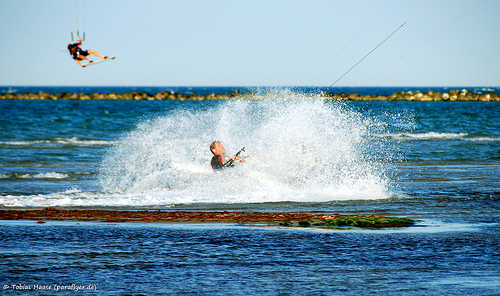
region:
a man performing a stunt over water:
[36, 22, 111, 65]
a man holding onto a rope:
[167, 100, 342, 201]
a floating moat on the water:
[57, 205, 420, 240]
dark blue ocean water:
[156, 235, 331, 294]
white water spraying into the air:
[269, 98, 380, 191]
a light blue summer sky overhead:
[122, 11, 471, 65]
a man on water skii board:
[61, 16, 136, 87]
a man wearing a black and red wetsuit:
[184, 131, 249, 173]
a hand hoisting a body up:
[72, 31, 85, 41]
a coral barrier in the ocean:
[370, 88, 489, 100]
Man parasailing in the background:
[55, 25, 138, 77]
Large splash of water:
[114, 98, 457, 199]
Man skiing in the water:
[185, 110, 319, 209]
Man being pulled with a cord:
[272, 27, 427, 94]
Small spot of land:
[184, 197, 471, 257]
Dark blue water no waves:
[117, 246, 260, 294]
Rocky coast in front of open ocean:
[150, 72, 255, 103]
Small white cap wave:
[399, 113, 495, 147]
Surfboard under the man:
[81, 52, 131, 65]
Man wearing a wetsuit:
[201, 137, 260, 176]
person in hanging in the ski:
[60, 25, 117, 76]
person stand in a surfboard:
[59, 33, 124, 79]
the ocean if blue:
[7, 76, 492, 293]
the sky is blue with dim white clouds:
[0, 3, 496, 85]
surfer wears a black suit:
[61, 33, 116, 75]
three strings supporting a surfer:
[60, 0, 97, 45]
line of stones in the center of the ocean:
[5, 79, 491, 111]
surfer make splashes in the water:
[99, 80, 402, 207]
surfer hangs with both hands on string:
[191, 128, 265, 191]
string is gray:
[328, 2, 448, 93]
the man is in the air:
[58, 12, 144, 91]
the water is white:
[100, 80, 390, 197]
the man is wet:
[191, 96, 366, 191]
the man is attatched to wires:
[167, 60, 422, 210]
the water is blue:
[12, 85, 459, 260]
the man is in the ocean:
[12, 46, 442, 274]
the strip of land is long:
[4, 199, 411, 237]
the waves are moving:
[359, 121, 476, 153]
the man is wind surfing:
[40, 24, 123, 71]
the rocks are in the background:
[257, 25, 497, 107]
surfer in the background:
[42, 34, 129, 84]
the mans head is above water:
[197, 129, 239, 171]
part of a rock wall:
[6, 80, 73, 101]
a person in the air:
[38, 26, 125, 88]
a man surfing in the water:
[176, 120, 288, 215]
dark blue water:
[193, 235, 277, 275]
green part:
[333, 213, 414, 236]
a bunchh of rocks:
[426, 78, 492, 109]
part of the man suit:
[210, 156, 232, 168]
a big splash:
[55, 86, 418, 213]